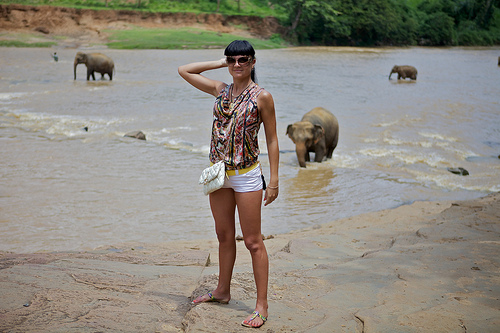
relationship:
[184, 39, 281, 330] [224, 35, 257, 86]
woman has hair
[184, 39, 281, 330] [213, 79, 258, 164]
woman wearing shirt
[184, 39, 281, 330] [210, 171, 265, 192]
woman wearing shorts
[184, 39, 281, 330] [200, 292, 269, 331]
woman wearing sandals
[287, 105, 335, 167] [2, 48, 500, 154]
elephant in water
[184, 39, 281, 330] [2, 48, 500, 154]
woman standing next to water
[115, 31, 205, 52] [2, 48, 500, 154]
grass next to water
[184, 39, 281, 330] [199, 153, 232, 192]
woman wearing handbag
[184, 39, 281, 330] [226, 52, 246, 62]
woman wearing sunglasses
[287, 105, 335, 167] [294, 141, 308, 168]
elephant has trunk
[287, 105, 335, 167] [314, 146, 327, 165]
elephant has leg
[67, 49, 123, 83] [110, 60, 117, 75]
elephant has tail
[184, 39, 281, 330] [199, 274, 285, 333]
woman standing on rock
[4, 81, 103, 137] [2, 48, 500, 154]
wave on water